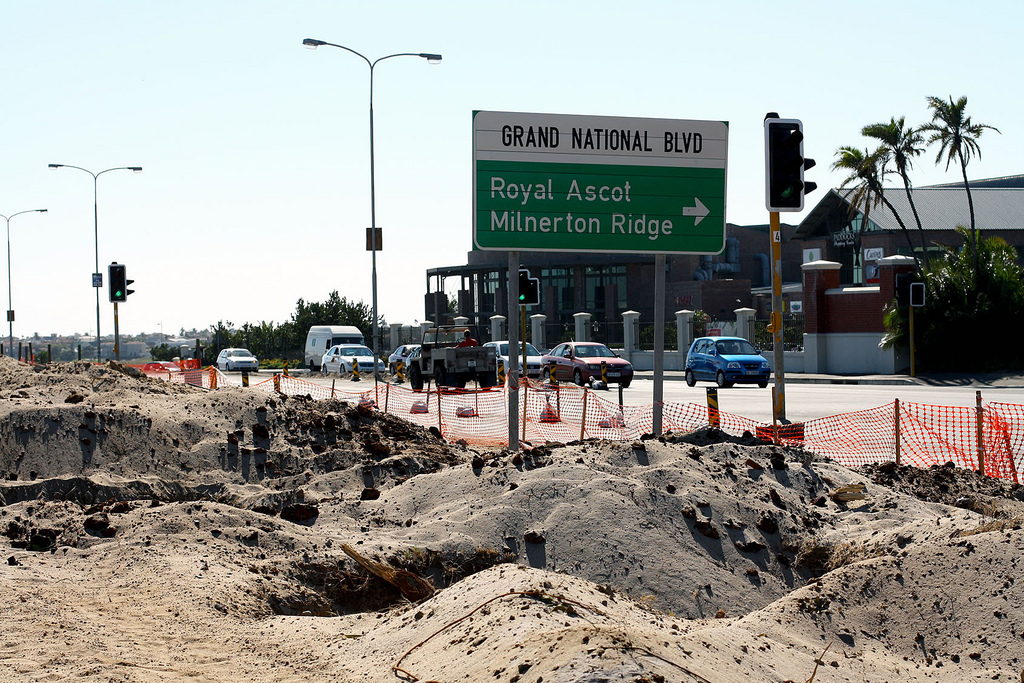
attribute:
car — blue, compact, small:
[681, 331, 773, 389]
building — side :
[784, 172, 992, 354]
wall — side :
[888, 249, 927, 343]